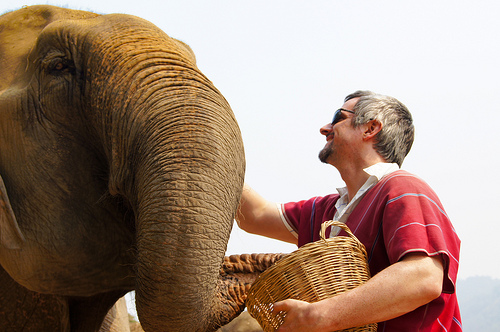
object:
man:
[235, 89, 464, 332]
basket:
[244, 220, 379, 331]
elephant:
[0, 4, 247, 332]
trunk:
[101, 28, 248, 332]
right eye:
[46, 60, 72, 76]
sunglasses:
[331, 108, 373, 124]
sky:
[0, 0, 500, 279]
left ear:
[362, 118, 383, 141]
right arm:
[234, 183, 337, 243]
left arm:
[309, 178, 446, 329]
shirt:
[277, 162, 462, 331]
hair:
[0, 2, 124, 15]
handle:
[319, 220, 360, 249]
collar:
[323, 162, 402, 236]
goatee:
[318, 139, 334, 164]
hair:
[343, 89, 415, 169]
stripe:
[385, 192, 450, 218]